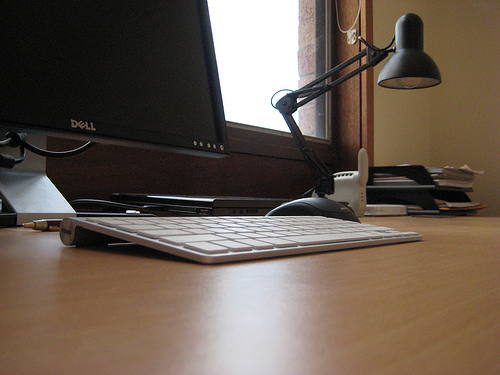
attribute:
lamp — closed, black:
[258, 13, 442, 223]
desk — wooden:
[1, 220, 499, 374]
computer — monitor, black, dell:
[4, 3, 244, 216]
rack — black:
[363, 159, 479, 217]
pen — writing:
[18, 214, 59, 235]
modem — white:
[306, 151, 375, 226]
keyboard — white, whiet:
[68, 201, 421, 257]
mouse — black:
[271, 192, 351, 225]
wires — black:
[8, 134, 102, 165]